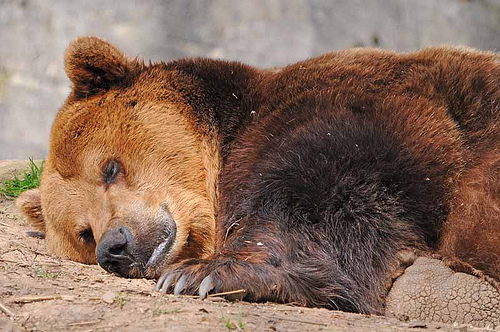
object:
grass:
[2, 156, 40, 187]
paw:
[371, 242, 498, 329]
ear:
[14, 185, 48, 230]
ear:
[46, 23, 134, 102]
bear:
[50, 46, 431, 231]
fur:
[144, 71, 462, 285]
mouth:
[136, 201, 177, 279]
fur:
[262, 107, 344, 182]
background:
[0, 0, 499, 61]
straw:
[15, 27, 225, 279]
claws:
[149, 270, 219, 300]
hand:
[155, 253, 305, 307]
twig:
[9, 287, 66, 306]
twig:
[179, 283, 245, 297]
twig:
[0, 302, 16, 320]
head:
[15, 37, 234, 259]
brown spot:
[424, 60, 495, 155]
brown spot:
[172, 58, 264, 143]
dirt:
[0, 197, 498, 329]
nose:
[84, 204, 152, 275]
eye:
[65, 218, 104, 255]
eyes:
[71, 145, 141, 189]